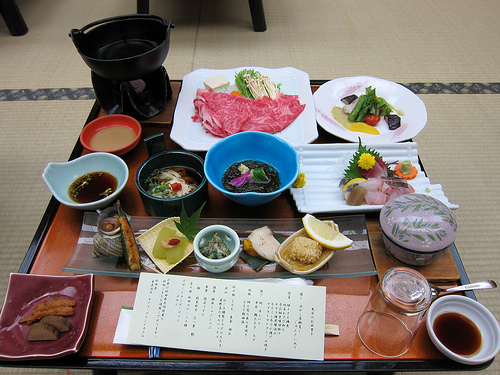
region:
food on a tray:
[0, 15, 496, 372]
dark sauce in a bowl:
[427, 296, 499, 368]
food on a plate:
[318, 71, 430, 146]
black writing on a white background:
[122, 268, 345, 360]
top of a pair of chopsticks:
[323, 318, 342, 337]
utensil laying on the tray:
[417, 282, 499, 294]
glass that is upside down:
[347, 266, 428, 358]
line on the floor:
[0, 75, 499, 112]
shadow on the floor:
[157, 4, 257, 29]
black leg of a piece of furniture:
[0, 1, 39, 36]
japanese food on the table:
[40, 8, 495, 373]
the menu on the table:
[113, 265, 348, 362]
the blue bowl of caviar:
[201, 133, 294, 195]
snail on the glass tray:
[70, 206, 137, 263]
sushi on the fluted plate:
[326, 139, 428, 212]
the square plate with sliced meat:
[167, 58, 317, 145]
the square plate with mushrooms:
[181, 63, 317, 152]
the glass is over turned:
[359, 271, 429, 358]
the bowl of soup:
[132, 142, 203, 203]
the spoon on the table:
[424, 268, 499, 293]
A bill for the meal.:
[122, 274, 340, 354]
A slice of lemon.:
[294, 206, 361, 253]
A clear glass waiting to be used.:
[352, 257, 439, 354]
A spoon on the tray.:
[419, 263, 495, 307]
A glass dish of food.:
[59, 209, 379, 276]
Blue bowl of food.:
[197, 127, 302, 208]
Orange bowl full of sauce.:
[72, 104, 147, 156]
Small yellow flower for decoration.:
[342, 143, 386, 178]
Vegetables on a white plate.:
[311, 72, 430, 146]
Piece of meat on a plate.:
[178, 84, 311, 137]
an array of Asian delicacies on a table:
[0, 13, 499, 363]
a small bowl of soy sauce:
[423, 295, 498, 362]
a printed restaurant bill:
[123, 271, 331, 361]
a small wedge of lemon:
[299, 213, 354, 254]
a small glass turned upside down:
[356, 265, 435, 360]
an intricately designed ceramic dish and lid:
[377, 191, 458, 266]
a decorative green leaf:
[172, 201, 205, 241]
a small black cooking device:
[65, 10, 174, 121]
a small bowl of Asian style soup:
[132, 130, 202, 215]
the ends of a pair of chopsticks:
[326, 320, 341, 337]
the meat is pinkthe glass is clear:
[381, 295, 399, 342]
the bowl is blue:
[229, 140, 259, 156]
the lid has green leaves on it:
[398, 210, 448, 245]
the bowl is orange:
[103, 116, 115, 126]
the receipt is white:
[216, 300, 263, 326]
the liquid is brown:
[450, 320, 467, 342]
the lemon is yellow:
[298, 210, 353, 257]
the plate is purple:
[19, 286, 41, 295]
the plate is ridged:
[308, 152, 327, 188]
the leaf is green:
[168, 200, 213, 238]